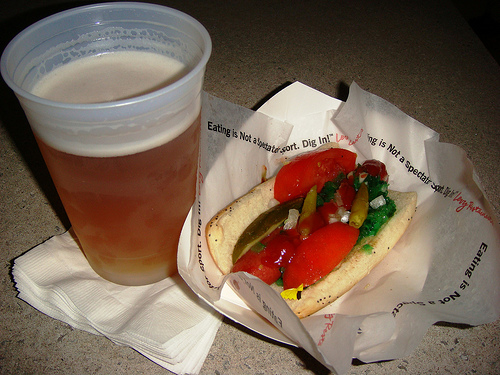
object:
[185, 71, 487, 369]
tissue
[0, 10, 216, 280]
drink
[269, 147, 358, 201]
tomato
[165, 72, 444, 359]
box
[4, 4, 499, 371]
table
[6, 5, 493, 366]
things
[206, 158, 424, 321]
bun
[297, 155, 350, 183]
peppers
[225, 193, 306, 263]
pickle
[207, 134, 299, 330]
side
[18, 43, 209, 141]
foam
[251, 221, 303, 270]
ketchup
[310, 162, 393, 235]
relish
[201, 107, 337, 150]
wording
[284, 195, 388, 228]
onion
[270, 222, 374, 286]
pepper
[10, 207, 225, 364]
napkins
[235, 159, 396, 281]
toppings